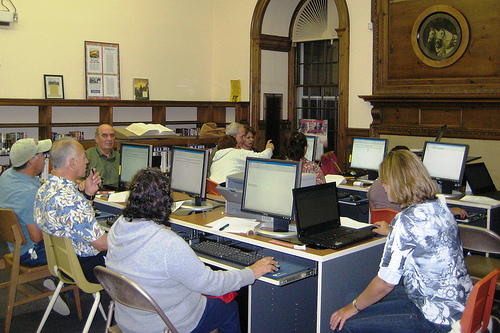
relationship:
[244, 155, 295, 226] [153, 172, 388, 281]
computers on desks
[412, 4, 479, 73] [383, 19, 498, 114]
design on wall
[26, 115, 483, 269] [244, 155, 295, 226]
people by computers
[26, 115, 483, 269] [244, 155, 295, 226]
people at computers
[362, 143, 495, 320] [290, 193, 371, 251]
lady uses laptop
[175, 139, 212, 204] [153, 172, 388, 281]
monitor on desk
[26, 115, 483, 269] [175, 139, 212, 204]
people around monitor